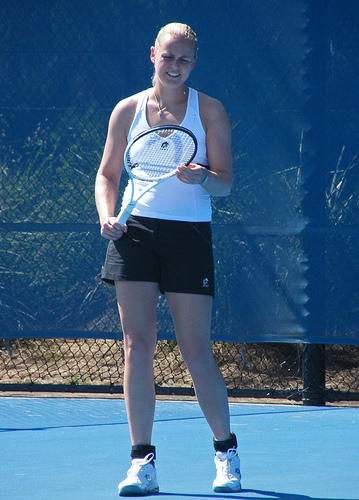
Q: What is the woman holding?
A: A tennis racket.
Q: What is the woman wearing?
A: Black shorts.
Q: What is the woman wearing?
A: White tennis shoes.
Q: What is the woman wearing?
A: A white sleeveless shirt.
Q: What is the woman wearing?
A: Ankle weights.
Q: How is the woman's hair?
A: In a ponytail.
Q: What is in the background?
A: A blue tarp.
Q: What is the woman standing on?
A: A blue tennis court.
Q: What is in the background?
A: A black chain linked fence.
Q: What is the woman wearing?
A: A necklace.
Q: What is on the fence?
A: Blue fabric.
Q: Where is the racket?
A: In woman's hand.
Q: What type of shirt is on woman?
A: Tank top.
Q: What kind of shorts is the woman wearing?
A: Black shorts.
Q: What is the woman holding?
A: A tennis racket.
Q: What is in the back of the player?
A: A fence.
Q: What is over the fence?
A: A tarp.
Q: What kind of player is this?
A: Tennis.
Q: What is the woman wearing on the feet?
A: Shoes.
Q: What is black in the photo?
A: A pair of shorts.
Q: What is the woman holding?
A: A tennis racket.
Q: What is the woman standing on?
A: A green tennis court.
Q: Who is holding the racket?
A: A woman.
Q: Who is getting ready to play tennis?
A: A young lady.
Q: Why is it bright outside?
A: It's daytime.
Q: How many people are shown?
A: One.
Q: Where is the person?
A: Tennis court.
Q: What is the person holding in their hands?
A: Racquet.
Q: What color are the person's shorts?
A: Black.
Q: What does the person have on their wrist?
A: Watch.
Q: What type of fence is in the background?
A: Chain link.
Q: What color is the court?
A: Blue.